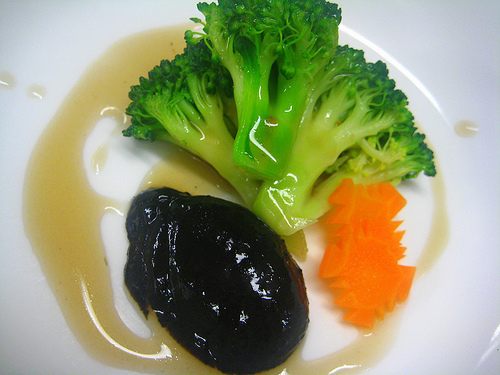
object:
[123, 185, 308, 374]
black shell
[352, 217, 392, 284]
orange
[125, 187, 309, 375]
fruit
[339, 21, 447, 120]
light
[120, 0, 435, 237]
broccolli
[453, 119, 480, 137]
sauce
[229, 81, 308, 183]
stem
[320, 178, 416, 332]
carrot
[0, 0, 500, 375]
dish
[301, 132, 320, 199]
stem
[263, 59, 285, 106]
space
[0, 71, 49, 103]
droplets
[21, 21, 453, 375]
liquid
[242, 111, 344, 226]
sauce